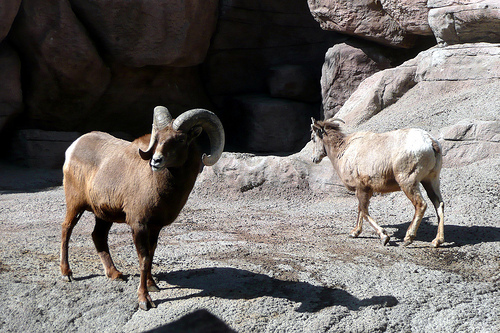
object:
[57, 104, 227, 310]
animals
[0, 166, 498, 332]
ground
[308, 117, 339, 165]
head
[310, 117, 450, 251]
animal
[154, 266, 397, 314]
shadow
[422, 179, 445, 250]
legs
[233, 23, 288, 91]
shadow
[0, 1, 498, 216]
background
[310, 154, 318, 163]
nose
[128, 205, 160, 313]
legs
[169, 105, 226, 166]
horns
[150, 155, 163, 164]
nose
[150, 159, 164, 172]
mouth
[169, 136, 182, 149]
eye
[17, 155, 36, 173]
part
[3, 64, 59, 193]
shade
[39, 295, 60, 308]
part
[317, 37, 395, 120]
rocks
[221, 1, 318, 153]
wall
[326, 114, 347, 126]
horn